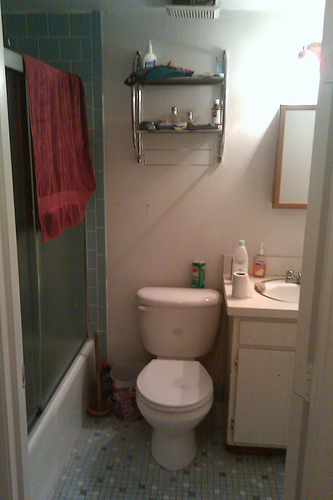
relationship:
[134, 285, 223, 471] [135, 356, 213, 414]
toilet has seat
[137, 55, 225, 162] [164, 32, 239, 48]
shelves on wall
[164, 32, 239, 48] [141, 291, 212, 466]
wall above toilet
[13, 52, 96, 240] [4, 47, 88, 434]
towel on shower door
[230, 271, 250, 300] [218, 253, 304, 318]
roll on counter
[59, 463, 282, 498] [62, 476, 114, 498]
floor has tiles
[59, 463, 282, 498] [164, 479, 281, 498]
floor has tiles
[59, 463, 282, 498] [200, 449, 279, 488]
floor has tiles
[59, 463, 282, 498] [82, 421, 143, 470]
floor has tiles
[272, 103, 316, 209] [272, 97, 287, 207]
mirror has frame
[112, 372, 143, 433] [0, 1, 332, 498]
waste basket in bathroom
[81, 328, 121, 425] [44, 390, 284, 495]
plunger on floor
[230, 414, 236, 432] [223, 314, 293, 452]
hinge on cabinetry